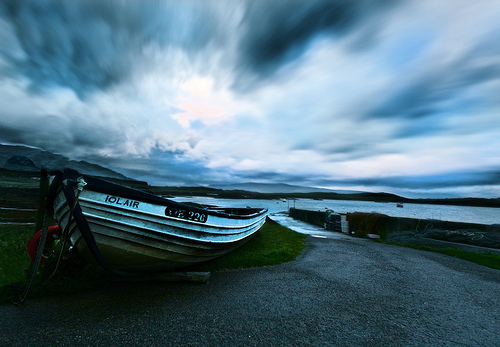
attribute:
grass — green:
[174, 212, 318, 268]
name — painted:
[100, 192, 141, 211]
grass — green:
[2, 171, 310, 278]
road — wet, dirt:
[5, 204, 498, 345]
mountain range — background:
[1, 139, 146, 185]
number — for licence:
[167, 204, 211, 229]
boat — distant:
[37, 151, 297, 291]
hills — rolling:
[1, 141, 138, 191]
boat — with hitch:
[21, 163, 275, 279]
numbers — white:
[165, 201, 216, 228]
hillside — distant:
[149, 184, 499, 206]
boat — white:
[71, 171, 277, 283]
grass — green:
[242, 225, 307, 270]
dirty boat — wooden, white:
[41, 170, 267, 259]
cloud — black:
[224, 0, 369, 92]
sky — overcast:
[0, 0, 498, 147]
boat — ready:
[38, 164, 273, 272]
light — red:
[25, 219, 60, 265]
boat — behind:
[32, 165, 267, 265]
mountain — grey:
[4, 145, 128, 180]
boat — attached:
[40, 132, 270, 252]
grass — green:
[230, 222, 303, 267]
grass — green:
[256, 216, 308, 265]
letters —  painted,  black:
[103, 191, 139, 210]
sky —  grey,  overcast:
[18, 10, 490, 147]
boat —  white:
[279, 198, 287, 202]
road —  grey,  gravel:
[7, 238, 497, 344]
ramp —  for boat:
[271, 213, 350, 236]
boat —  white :
[49, 166, 271, 268]